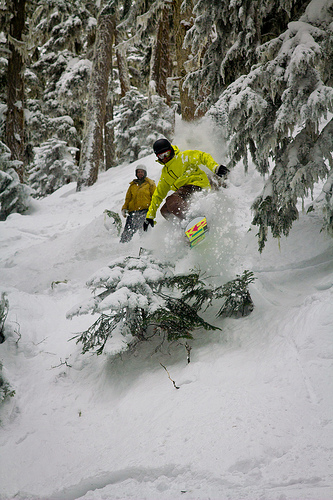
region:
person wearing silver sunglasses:
[151, 148, 173, 162]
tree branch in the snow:
[63, 230, 239, 356]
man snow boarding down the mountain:
[163, 180, 238, 271]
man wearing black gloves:
[213, 164, 232, 177]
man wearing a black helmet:
[151, 136, 173, 161]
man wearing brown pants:
[145, 183, 213, 228]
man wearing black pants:
[121, 202, 152, 241]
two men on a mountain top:
[102, 139, 242, 259]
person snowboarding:
[141, 133, 237, 255]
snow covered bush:
[63, 250, 261, 381]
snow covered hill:
[5, 146, 331, 499]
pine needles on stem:
[69, 313, 109, 359]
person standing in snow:
[113, 161, 155, 246]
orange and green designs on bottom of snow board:
[174, 212, 217, 254]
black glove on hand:
[212, 160, 234, 184]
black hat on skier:
[151, 133, 182, 166]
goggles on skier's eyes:
[151, 146, 179, 164]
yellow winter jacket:
[118, 177, 157, 211]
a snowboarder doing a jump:
[128, 121, 256, 300]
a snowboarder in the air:
[117, 112, 254, 257]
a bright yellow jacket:
[131, 143, 234, 208]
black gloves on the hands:
[215, 163, 234, 186]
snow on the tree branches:
[57, 2, 332, 362]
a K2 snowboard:
[172, 215, 225, 272]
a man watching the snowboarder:
[91, 146, 171, 256]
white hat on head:
[127, 162, 153, 177]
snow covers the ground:
[24, 154, 331, 496]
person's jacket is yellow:
[133, 135, 230, 241]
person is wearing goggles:
[148, 135, 181, 170]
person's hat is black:
[150, 137, 178, 166]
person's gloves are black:
[138, 162, 235, 235]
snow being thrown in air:
[132, 177, 257, 282]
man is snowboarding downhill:
[138, 133, 234, 250]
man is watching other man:
[114, 125, 230, 261]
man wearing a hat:
[134, 159, 152, 185]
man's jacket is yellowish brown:
[121, 161, 156, 213]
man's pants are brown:
[157, 188, 200, 220]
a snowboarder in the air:
[83, 93, 282, 284]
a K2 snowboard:
[173, 207, 222, 282]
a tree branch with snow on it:
[45, 218, 277, 356]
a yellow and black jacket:
[144, 132, 225, 204]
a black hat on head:
[152, 134, 180, 162]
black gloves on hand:
[209, 160, 245, 189]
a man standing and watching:
[105, 152, 163, 250]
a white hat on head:
[130, 158, 152, 181]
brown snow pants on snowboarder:
[144, 172, 222, 226]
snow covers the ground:
[6, 178, 331, 498]